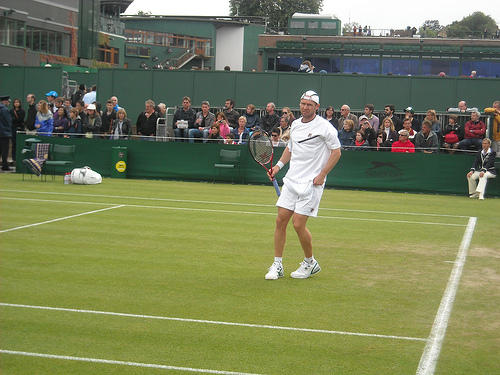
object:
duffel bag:
[63, 166, 103, 184]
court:
[1, 172, 500, 375]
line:
[0, 301, 426, 342]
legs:
[290, 188, 319, 263]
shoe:
[263, 263, 285, 281]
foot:
[264, 262, 282, 280]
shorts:
[274, 172, 324, 218]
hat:
[299, 88, 321, 104]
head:
[298, 89, 319, 120]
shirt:
[284, 115, 339, 184]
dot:
[113, 159, 128, 174]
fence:
[17, 132, 500, 197]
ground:
[0, 172, 500, 374]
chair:
[43, 143, 75, 183]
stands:
[33, 108, 499, 153]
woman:
[345, 132, 370, 153]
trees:
[230, 0, 324, 34]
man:
[390, 130, 416, 153]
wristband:
[274, 160, 286, 168]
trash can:
[109, 146, 128, 180]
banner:
[16, 134, 499, 195]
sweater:
[390, 139, 412, 152]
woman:
[466, 136, 498, 202]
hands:
[310, 176, 325, 188]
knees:
[466, 175, 478, 180]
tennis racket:
[246, 130, 282, 197]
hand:
[264, 166, 277, 180]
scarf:
[298, 88, 322, 106]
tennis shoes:
[290, 257, 322, 278]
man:
[263, 90, 342, 283]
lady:
[212, 113, 229, 138]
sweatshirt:
[215, 121, 230, 136]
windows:
[56, 34, 62, 55]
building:
[2, 0, 500, 79]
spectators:
[456, 111, 486, 149]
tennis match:
[0, 88, 500, 374]